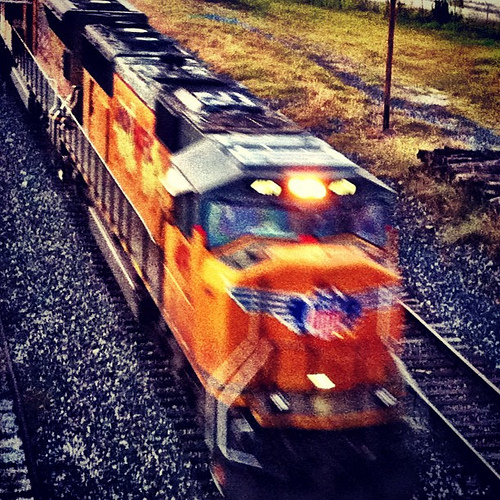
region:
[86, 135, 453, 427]
Train running in the track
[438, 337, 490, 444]
Train track with metal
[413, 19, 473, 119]
Green color grass with dirt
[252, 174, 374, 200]
Head light of the train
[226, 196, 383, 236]
Forn glass with wiper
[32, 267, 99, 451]
Crushed stone near the train track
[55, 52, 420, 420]
Engine of the train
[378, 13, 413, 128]
Metal post near the track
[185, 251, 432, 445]
Front portion of the engine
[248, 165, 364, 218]
Head light glowing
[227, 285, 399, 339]
a blurry white and blue logo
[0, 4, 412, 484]
a bright orange train in motion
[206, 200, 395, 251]
front windshield of a train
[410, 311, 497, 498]
black train tracks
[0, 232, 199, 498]
gravel between train tracks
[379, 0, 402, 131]
a thin wooden tree trunk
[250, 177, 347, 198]
a bright light on the front of a train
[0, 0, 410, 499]
a large orange train in motion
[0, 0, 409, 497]
a speeding orange train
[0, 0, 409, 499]
a large orange train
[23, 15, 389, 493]
train on the track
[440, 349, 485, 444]
tracks for trains to travel on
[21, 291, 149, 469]
rocks next to track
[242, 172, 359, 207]
lights on the train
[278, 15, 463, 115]
green area next to track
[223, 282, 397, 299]
image on the train car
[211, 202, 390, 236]
window on the train car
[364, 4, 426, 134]
pole in the ground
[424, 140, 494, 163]
logs of wood on ground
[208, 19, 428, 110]
bare trail in grass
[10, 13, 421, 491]
train traveling down the tracks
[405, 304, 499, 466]
train tracks not in use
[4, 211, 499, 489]
gravel around train tracks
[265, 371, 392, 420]
lights on front of train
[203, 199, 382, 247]
front windows of train car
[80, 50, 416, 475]
orange front train car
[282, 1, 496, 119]
grass patch beside gravel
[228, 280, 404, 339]
blue and red logo on the front of the train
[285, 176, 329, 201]
light above front windows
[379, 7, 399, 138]
utility pole next to train tracks